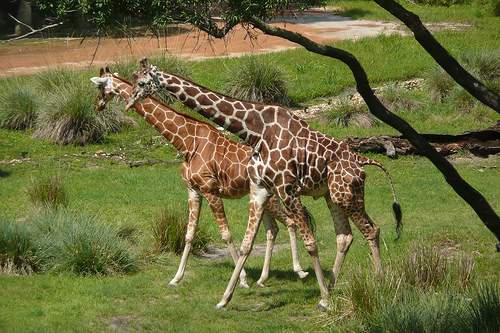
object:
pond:
[1, 21, 360, 71]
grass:
[3, 65, 498, 332]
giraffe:
[127, 60, 403, 311]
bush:
[34, 79, 126, 143]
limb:
[365, 0, 500, 122]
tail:
[353, 159, 401, 243]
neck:
[158, 69, 268, 155]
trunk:
[350, 123, 499, 154]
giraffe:
[89, 63, 307, 284]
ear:
[89, 74, 107, 87]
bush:
[32, 210, 135, 273]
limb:
[160, 2, 498, 253]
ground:
[275, 1, 444, 43]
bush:
[224, 53, 290, 113]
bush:
[1, 77, 42, 133]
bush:
[146, 203, 211, 252]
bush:
[23, 172, 68, 212]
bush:
[1, 212, 58, 279]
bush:
[368, 282, 499, 332]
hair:
[391, 197, 406, 241]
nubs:
[156, 74, 172, 82]